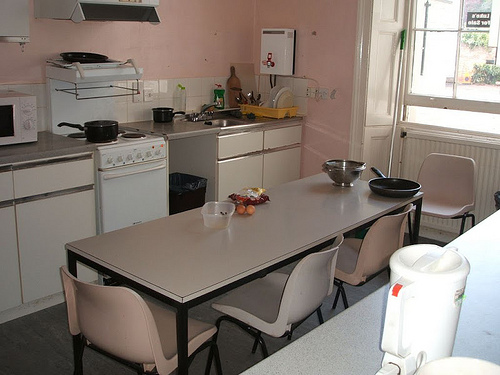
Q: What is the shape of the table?
A: It is rectangular.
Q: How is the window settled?
A: It's Slightly open.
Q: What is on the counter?
A: White Kettle.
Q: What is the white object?
A: Electric kettle.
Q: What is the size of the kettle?
A: It's big.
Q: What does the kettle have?
A: Red tab.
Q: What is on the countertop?
A: White electric kettle.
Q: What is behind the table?
A: Kettle on counter.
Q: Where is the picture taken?
A: A kitchen.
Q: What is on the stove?
A: A black pan.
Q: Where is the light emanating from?
A: The window.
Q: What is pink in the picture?
A: The walls.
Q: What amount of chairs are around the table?
A: 4.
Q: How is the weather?
A: Sunny.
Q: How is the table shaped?
A: Rectangle.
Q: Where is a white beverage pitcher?
A: Counter on right.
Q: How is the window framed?
A: White trim.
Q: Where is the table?
A: In middle of room.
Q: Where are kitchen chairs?
A: Around the table.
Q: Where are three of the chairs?
A: Under the table.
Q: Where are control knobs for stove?
A: On the front.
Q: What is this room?
A: A kitchen.